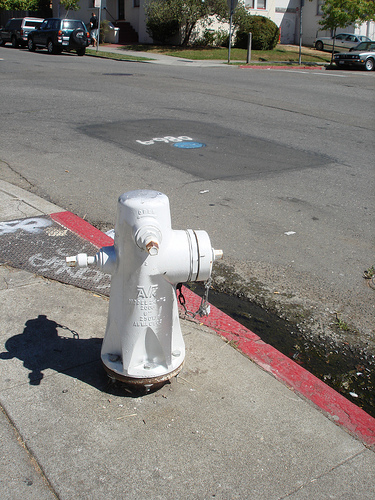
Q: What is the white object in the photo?
A: Fire hydrant.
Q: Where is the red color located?
A: Curb.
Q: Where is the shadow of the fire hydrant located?
A: Sidewalk.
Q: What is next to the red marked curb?
A: Puddle.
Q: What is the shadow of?
A: Fire hydrant.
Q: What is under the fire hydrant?
A: Red line.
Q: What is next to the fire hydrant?
A: Puddle.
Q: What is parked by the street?
A: Cars.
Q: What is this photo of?
A: The street.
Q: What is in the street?
A: Parked cars.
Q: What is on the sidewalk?
A: A fire hydrant.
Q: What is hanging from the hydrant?
A: A chain.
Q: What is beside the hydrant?
A: A metal plate.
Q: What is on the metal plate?
A: Grafitti.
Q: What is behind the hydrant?
A: Its shadow.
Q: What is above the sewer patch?
A: A number.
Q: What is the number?
A: 6980.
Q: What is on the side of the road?
A: Fire hydrant.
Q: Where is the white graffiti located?
A: Sidewalk.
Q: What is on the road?
A: Puddle of water.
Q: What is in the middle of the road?
A: Dark patch.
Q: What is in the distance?
A: Houses.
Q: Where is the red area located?
A: Sidewalk.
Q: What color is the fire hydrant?
A: White.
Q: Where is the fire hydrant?
A: On the sidewalk.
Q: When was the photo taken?
A: In the daytime.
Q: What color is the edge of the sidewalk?
A: Red.